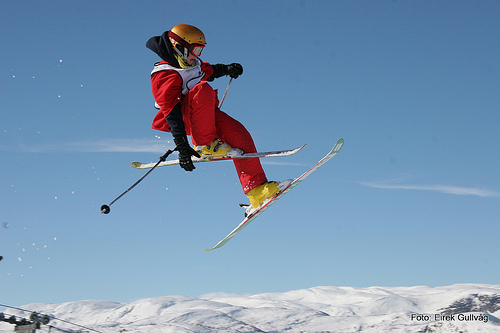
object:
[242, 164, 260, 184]
red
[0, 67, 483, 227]
distance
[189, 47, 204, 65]
face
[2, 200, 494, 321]
ground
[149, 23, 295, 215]
skier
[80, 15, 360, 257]
trick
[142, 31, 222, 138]
hoody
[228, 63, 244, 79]
gloves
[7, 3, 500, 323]
air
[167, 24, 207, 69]
helmet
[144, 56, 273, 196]
jump suit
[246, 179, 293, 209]
boots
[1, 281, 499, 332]
mountains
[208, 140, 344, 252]
skis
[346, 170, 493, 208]
clouds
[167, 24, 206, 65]
head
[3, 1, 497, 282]
sky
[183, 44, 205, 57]
goggles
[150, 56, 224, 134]
sweatshirt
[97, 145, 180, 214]
pole